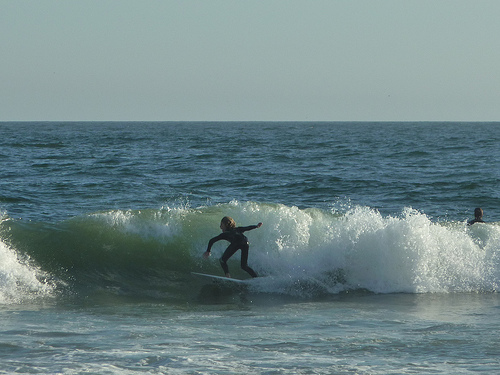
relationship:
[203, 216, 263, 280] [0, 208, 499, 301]
sufer riding wave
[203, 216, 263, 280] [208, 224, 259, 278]
sufer wearing wetsuit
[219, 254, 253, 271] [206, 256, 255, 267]
knees bent down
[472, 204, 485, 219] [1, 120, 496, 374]
head above water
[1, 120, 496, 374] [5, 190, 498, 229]
water splashing high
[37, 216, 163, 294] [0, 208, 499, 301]
break in wave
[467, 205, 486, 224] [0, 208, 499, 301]
person behind wave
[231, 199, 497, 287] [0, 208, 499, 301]
foam on wave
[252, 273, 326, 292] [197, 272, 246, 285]
trail of surfboard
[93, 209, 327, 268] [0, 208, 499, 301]
swell of wave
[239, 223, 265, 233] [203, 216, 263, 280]
arm of sufer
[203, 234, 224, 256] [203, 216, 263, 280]
arm of sufer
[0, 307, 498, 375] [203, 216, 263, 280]
water behind sufer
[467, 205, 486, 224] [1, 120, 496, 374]
person in water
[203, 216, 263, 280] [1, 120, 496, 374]
sufer in water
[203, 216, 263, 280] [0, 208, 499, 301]
sufer surfing wave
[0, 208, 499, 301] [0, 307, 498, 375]
wave in water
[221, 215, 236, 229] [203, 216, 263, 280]
hair on sufer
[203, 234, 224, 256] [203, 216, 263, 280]
arm on sufer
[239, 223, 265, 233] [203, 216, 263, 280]
arm on sufer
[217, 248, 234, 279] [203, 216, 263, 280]
leg on sufer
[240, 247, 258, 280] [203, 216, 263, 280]
leg on sufer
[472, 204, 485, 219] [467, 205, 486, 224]
head of person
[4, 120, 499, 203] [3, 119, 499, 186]
water in distance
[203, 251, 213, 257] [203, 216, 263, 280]
hand of sufer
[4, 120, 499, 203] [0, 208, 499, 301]
water behind wave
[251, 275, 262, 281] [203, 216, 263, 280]
foot of sufer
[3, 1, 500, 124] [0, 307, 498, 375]
sky above water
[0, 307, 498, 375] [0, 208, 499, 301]
water in front wave